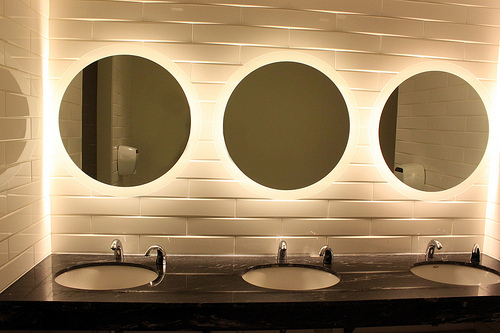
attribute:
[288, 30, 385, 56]
brick — ceramic, rectangular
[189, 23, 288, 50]
brick — ceramic, rectangular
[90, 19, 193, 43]
brick — ceramic, rectangular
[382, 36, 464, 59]
brick — ceramic, rectangular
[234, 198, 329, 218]
brick — ceramic, rectangular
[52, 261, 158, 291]
sink — white, shiny, round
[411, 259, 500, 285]
sink — white, shiny, round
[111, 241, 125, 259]
faucet — silver, automatic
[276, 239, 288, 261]
faucet — silver, automatic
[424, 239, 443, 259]
faucet — silver, automatic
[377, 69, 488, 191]
mirror — circular, round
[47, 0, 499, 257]
wall — white, bathroom wall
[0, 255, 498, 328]
counter — concrete, marble, black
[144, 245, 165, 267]
soap dispenser — automatic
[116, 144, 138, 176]
hand dryer — reflected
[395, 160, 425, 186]
hand dryer — reflected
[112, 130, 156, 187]
soap dispensor — white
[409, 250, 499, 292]
sink — round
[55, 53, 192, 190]
mirror — circular, round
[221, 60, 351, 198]
mirror — circular, round, cicular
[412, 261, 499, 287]
sink — three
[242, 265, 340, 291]
sink — white, shiny, round, three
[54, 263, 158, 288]
sink — three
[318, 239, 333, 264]
soap dispenser — automatic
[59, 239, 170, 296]
sink — three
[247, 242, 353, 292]
sink — three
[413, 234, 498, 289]
sink — three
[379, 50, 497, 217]
mirror — three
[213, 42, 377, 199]
mirror — three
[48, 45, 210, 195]
mirror — three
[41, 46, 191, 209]
mirror — cicular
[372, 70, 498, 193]
mirror — cicular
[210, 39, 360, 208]
circle mirror — circular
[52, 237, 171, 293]
sink — three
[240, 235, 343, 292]
sink — three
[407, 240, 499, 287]
sink — three